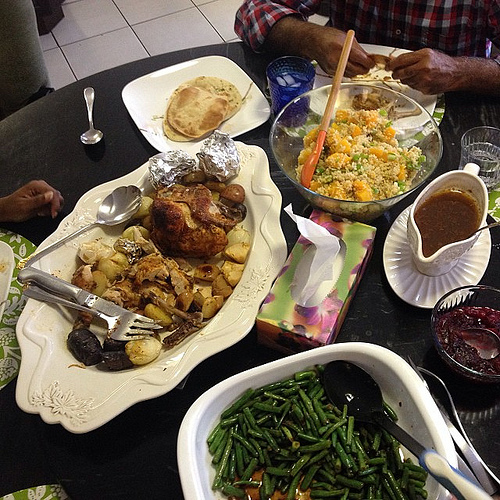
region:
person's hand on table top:
[10, 174, 72, 210]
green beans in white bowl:
[241, 413, 357, 462]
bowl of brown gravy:
[410, 171, 492, 258]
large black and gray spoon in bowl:
[320, 363, 459, 470]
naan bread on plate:
[163, 71, 241, 130]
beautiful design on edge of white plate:
[28, 383, 95, 410]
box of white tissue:
[263, 213, 379, 321]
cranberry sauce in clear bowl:
[441, 307, 493, 357]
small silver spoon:
[66, 80, 111, 150]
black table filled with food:
[61, 80, 473, 336]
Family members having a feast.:
[48, 38, 495, 496]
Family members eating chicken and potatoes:
[26, 130, 261, 375]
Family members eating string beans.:
[176, 343, 426, 495]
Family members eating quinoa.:
[281, 75, 432, 205]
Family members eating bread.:
[139, 74, 250, 136]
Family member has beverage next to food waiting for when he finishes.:
[268, 29, 446, 103]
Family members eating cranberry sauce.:
[422, 289, 498, 382]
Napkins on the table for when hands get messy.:
[271, 200, 372, 342]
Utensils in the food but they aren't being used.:
[0, 40, 498, 497]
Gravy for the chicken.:
[393, 175, 485, 262]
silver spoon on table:
[80, 81, 102, 150]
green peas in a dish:
[259, 420, 323, 474]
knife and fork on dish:
[8, 266, 159, 343]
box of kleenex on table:
[266, 208, 374, 351]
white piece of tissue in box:
[284, 206, 339, 297]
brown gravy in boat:
[423, 199, 466, 238]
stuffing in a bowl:
[342, 134, 372, 186]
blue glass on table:
[271, 49, 313, 113]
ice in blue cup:
[276, 71, 304, 88]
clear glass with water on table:
[458, 120, 498, 179]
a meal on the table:
[19, 27, 470, 430]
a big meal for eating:
[47, 83, 465, 427]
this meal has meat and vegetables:
[97, 109, 478, 499]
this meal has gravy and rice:
[140, 23, 490, 348]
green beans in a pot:
[196, 351, 421, 496]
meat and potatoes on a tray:
[38, 166, 288, 377]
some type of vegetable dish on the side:
[280, 56, 438, 232]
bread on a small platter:
[125, 48, 270, 153]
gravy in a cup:
[396, 148, 492, 289]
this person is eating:
[230, 7, 474, 100]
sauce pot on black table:
[404, 159, 487, 279]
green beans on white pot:
[201, 372, 426, 498]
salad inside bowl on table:
[299, 105, 424, 206]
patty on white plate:
[162, 75, 243, 137]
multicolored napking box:
[252, 208, 382, 343]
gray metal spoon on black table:
[75, 82, 102, 147]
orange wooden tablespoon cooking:
[300, 30, 357, 190]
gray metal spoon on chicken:
[20, 183, 142, 270]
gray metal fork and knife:
[20, 270, 161, 347]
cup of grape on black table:
[434, 280, 499, 425]